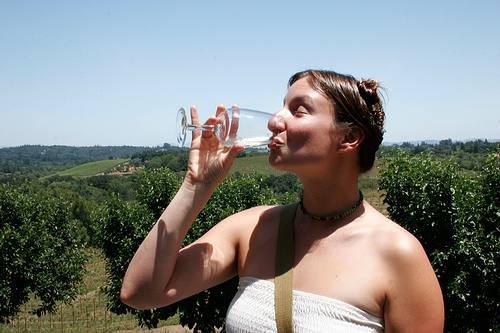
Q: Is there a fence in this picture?
A: Yes, there is a fence.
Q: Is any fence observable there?
A: Yes, there is a fence.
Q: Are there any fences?
A: Yes, there is a fence.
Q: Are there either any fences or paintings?
A: Yes, there is a fence.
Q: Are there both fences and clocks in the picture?
A: No, there is a fence but no clocks.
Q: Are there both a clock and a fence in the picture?
A: No, there is a fence but no clocks.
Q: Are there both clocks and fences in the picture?
A: No, there is a fence but no clocks.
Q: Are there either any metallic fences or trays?
A: Yes, there is a metal fence.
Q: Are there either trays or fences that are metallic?
A: Yes, the fence is metallic.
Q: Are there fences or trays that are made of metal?
A: Yes, the fence is made of metal.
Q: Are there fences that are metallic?
A: Yes, there is a metal fence.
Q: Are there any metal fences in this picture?
A: Yes, there is a metal fence.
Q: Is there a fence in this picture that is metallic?
A: Yes, there is a fence that is metallic.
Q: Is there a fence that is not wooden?
A: Yes, there is a metallic fence.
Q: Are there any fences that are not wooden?
A: Yes, there is a metallic fence.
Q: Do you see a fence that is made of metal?
A: Yes, there is a fence that is made of metal.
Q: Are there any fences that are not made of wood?
A: Yes, there is a fence that is made of metal.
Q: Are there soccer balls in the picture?
A: No, there are no soccer balls.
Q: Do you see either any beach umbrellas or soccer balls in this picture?
A: No, there are no soccer balls or beach umbrellas.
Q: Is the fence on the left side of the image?
A: Yes, the fence is on the left of the image.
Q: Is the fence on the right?
A: No, the fence is on the left of the image.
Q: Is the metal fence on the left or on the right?
A: The fence is on the left of the image.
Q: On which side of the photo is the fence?
A: The fence is on the left of the image.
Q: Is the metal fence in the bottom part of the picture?
A: Yes, the fence is in the bottom of the image.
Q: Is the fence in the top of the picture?
A: No, the fence is in the bottom of the image.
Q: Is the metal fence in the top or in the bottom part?
A: The fence is in the bottom of the image.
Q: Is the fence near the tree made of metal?
A: Yes, the fence is made of metal.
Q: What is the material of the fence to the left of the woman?
A: The fence is made of metal.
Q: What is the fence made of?
A: The fence is made of metal.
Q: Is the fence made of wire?
A: No, the fence is made of metal.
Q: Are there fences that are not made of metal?
A: No, there is a fence but it is made of metal.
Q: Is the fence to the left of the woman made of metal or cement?
A: The fence is made of metal.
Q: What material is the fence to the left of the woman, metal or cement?
A: The fence is made of metal.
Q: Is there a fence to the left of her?
A: Yes, there is a fence to the left of the woman.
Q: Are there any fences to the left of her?
A: Yes, there is a fence to the left of the woman.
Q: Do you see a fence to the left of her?
A: Yes, there is a fence to the left of the woman.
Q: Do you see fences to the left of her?
A: Yes, there is a fence to the left of the woman.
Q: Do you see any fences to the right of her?
A: No, the fence is to the left of the woman.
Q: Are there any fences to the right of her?
A: No, the fence is to the left of the woman.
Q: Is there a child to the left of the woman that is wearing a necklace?
A: No, there is a fence to the left of the woman.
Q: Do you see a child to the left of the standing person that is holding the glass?
A: No, there is a fence to the left of the woman.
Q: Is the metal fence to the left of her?
A: Yes, the fence is to the left of a woman.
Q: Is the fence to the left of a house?
A: No, the fence is to the left of a woman.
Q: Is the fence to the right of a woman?
A: No, the fence is to the left of a woman.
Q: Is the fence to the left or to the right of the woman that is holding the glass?
A: The fence is to the left of the woman.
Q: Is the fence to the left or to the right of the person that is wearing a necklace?
A: The fence is to the left of the woman.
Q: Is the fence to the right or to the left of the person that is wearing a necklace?
A: The fence is to the left of the woman.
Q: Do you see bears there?
A: No, there are no bears.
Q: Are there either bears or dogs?
A: No, there are no bears or dogs.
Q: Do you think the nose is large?
A: Yes, the nose is large.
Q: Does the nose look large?
A: Yes, the nose is large.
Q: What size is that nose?
A: The nose is large.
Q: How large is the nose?
A: The nose is large.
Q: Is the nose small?
A: No, the nose is large.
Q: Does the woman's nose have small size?
A: No, the nose is large.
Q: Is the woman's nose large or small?
A: The nose is large.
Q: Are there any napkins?
A: No, there are no napkins.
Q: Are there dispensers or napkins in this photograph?
A: No, there are no napkins or dispensers.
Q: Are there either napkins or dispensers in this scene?
A: No, there are no napkins or dispensers.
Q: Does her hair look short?
A: Yes, the hair is short.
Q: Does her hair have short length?
A: Yes, the hair is short.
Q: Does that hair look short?
A: Yes, the hair is short.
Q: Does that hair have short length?
A: Yes, the hair is short.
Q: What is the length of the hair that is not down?
A: The hair is short.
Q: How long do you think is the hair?
A: The hair is short.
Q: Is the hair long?
A: No, the hair is short.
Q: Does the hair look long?
A: No, the hair is short.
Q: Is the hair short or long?
A: The hair is short.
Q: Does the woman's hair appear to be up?
A: Yes, the hair is up.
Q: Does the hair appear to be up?
A: Yes, the hair is up.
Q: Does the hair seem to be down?
A: No, the hair is up.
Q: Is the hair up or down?
A: The hair is up.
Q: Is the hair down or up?
A: The hair is up.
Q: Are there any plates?
A: No, there are no plates.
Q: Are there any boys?
A: No, there are no boys.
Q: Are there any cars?
A: No, there are no cars.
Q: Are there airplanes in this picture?
A: No, there are no airplanes.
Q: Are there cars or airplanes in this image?
A: No, there are no airplanes or cars.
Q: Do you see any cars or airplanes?
A: No, there are no airplanes or cars.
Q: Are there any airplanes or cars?
A: No, there are no airplanes or cars.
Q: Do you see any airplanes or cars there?
A: No, there are no airplanes or cars.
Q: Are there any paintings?
A: No, there are no paintings.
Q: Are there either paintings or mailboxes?
A: No, there are no paintings or mailboxes.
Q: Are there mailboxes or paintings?
A: No, there are no paintings or mailboxes.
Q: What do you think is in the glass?
A: The liquid is in the glass.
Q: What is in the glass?
A: The liquid is in the glass.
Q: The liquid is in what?
A: The liquid is in the glass.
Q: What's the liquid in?
A: The liquid is in the glass.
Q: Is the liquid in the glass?
A: Yes, the liquid is in the glass.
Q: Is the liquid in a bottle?
A: No, the liquid is in the glass.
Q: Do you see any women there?
A: Yes, there is a woman.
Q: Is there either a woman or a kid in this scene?
A: Yes, there is a woman.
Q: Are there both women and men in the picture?
A: No, there is a woman but no men.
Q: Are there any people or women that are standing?
A: Yes, the woman is standing.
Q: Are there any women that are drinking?
A: Yes, there is a woman that is drinking.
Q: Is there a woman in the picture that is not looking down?
A: Yes, there is a woman that is drinking.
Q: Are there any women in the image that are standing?
A: Yes, there is a woman that is standing.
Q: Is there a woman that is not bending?
A: Yes, there is a woman that is standing.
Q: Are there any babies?
A: No, there are no babies.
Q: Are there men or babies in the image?
A: No, there are no babies or men.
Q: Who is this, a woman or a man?
A: This is a woman.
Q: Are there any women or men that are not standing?
A: No, there is a woman but she is standing.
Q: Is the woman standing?
A: Yes, the woman is standing.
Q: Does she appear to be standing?
A: Yes, the woman is standing.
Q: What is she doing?
A: The woman is standing.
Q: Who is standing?
A: The woman is standing.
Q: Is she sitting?
A: No, the woman is standing.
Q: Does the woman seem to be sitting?
A: No, the woman is standing.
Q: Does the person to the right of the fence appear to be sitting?
A: No, the woman is standing.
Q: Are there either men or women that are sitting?
A: No, there is a woman but she is standing.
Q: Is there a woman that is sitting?
A: No, there is a woman but she is standing.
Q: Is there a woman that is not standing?
A: No, there is a woman but she is standing.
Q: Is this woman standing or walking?
A: The woman is standing.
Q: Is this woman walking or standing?
A: The woman is standing.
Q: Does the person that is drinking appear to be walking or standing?
A: The woman is standing.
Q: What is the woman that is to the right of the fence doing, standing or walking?
A: The woman is standing.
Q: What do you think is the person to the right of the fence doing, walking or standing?
A: The woman is standing.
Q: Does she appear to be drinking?
A: Yes, the woman is drinking.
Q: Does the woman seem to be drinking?
A: Yes, the woman is drinking.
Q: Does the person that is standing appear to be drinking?
A: Yes, the woman is drinking.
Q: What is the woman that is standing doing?
A: The woman is drinking.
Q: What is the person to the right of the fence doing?
A: The woman is drinking.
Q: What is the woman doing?
A: The woman is drinking.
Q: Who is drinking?
A: The woman is drinking.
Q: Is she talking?
A: No, the woman is drinking.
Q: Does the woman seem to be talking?
A: No, the woman is drinking.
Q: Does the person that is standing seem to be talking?
A: No, the woman is drinking.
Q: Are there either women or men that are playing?
A: No, there is a woman but she is drinking.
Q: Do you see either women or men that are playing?
A: No, there is a woman but she is drinking.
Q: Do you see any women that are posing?
A: No, there is a woman but she is drinking.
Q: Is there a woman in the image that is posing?
A: No, there is a woman but she is drinking.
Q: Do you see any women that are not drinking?
A: No, there is a woman but she is drinking.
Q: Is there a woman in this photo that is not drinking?
A: No, there is a woman but she is drinking.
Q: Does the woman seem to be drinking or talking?
A: The woman is drinking.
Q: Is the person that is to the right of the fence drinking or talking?
A: The woman is drinking.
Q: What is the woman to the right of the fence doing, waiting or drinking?
A: The woman is drinking.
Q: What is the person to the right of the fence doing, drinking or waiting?
A: The woman is drinking.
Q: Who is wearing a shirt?
A: The woman is wearing a shirt.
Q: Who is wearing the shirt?
A: The woman is wearing a shirt.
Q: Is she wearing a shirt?
A: Yes, the woman is wearing a shirt.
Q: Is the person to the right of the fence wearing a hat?
A: No, the woman is wearing a shirt.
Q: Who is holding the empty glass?
A: The woman is holding the glass.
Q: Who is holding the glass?
A: The woman is holding the glass.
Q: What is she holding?
A: The woman is holding the glass.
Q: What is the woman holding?
A: The woman is holding the glass.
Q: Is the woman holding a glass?
A: Yes, the woman is holding a glass.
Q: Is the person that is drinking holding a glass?
A: Yes, the woman is holding a glass.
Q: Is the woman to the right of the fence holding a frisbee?
A: No, the woman is holding a glass.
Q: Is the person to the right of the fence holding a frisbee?
A: No, the woman is holding a glass.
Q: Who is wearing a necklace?
A: The woman is wearing a necklace.